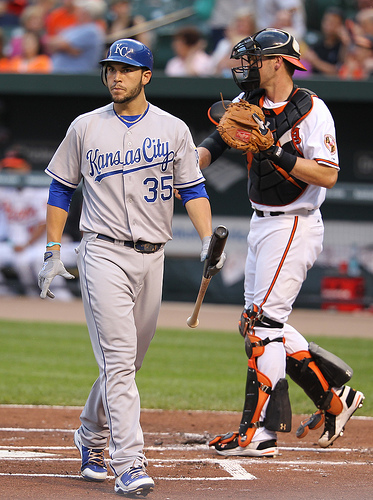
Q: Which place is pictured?
A: It is a field.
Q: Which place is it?
A: It is a field.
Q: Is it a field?
A: Yes, it is a field.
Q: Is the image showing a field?
A: Yes, it is showing a field.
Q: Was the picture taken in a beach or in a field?
A: It was taken at a field.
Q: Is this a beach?
A: No, it is a field.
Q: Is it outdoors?
A: Yes, it is outdoors.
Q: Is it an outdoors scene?
A: Yes, it is outdoors.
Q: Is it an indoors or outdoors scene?
A: It is outdoors.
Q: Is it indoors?
A: No, it is outdoors.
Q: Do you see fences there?
A: No, there are no fences.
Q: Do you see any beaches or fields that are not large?
A: No, there is a field but it is large.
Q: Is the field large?
A: Yes, the field is large.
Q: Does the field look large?
A: Yes, the field is large.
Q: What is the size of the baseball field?
A: The field is large.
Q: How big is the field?
A: The field is large.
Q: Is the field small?
A: No, the field is large.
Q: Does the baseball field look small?
A: No, the field is large.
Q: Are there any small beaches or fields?
A: No, there is a field but it is large.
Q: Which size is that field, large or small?
A: The field is large.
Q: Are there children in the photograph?
A: No, there are no children.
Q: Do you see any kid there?
A: No, there are no children.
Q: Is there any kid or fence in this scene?
A: No, there are no children or fences.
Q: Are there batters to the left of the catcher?
A: Yes, there is a batter to the left of the catcher.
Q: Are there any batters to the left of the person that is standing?
A: Yes, there is a batter to the left of the catcher.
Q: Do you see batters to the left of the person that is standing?
A: Yes, there is a batter to the left of the catcher.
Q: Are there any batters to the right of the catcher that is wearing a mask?
A: No, the batter is to the left of the catcher.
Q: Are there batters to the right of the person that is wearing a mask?
A: No, the batter is to the left of the catcher.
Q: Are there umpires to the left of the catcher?
A: No, there is a batter to the left of the catcher.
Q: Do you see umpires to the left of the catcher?
A: No, there is a batter to the left of the catcher.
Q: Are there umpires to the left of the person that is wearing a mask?
A: No, there is a batter to the left of the catcher.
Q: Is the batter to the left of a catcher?
A: Yes, the batter is to the left of a catcher.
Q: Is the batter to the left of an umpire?
A: No, the batter is to the left of a catcher.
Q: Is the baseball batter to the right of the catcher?
A: No, the batter is to the left of the catcher.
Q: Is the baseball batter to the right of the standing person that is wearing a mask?
A: No, the batter is to the left of the catcher.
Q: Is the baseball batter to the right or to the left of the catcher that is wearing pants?
A: The batter is to the left of the catcher.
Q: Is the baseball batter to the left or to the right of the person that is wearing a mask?
A: The batter is to the left of the catcher.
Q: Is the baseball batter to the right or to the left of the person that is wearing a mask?
A: The batter is to the left of the catcher.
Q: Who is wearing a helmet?
A: The batter is wearing a helmet.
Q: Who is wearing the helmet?
A: The batter is wearing a helmet.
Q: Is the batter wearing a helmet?
A: Yes, the batter is wearing a helmet.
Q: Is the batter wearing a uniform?
A: No, the batter is wearing a helmet.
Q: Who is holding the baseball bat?
A: The batter is holding the baseball bat.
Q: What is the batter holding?
A: The batter is holding the baseball bat.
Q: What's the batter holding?
A: The batter is holding the baseball bat.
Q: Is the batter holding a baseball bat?
A: Yes, the batter is holding a baseball bat.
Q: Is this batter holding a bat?
A: No, the batter is holding a baseball bat.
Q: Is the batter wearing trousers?
A: Yes, the batter is wearing trousers.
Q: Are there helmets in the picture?
A: Yes, there is a helmet.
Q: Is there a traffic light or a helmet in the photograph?
A: Yes, there is a helmet.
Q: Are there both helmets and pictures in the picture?
A: No, there is a helmet but no pictures.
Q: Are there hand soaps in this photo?
A: No, there are no hand soaps.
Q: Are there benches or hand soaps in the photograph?
A: No, there are no hand soaps or benches.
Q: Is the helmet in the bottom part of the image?
A: No, the helmet is in the top of the image.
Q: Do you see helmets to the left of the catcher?
A: Yes, there is a helmet to the left of the catcher.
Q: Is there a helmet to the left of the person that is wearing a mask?
A: Yes, there is a helmet to the left of the catcher.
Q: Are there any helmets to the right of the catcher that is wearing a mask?
A: No, the helmet is to the left of the catcher.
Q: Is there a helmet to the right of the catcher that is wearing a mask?
A: No, the helmet is to the left of the catcher.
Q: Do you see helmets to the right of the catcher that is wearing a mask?
A: No, the helmet is to the left of the catcher.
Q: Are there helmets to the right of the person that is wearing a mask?
A: No, the helmet is to the left of the catcher.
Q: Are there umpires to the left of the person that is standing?
A: No, there is a helmet to the left of the catcher.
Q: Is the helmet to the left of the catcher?
A: Yes, the helmet is to the left of the catcher.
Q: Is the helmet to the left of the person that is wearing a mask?
A: Yes, the helmet is to the left of the catcher.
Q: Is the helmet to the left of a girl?
A: No, the helmet is to the left of the catcher.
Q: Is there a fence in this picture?
A: No, there are no fences.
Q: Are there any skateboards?
A: No, there are no skateboards.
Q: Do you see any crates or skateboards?
A: No, there are no skateboards or crates.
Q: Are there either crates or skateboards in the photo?
A: No, there are no skateboards or crates.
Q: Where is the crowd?
A: The crowd is in the bleachers.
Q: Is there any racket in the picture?
A: No, there are no rackets.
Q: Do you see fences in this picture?
A: No, there are no fences.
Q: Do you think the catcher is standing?
A: Yes, the catcher is standing.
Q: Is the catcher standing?
A: Yes, the catcher is standing.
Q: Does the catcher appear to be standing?
A: Yes, the catcher is standing.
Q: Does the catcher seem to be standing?
A: Yes, the catcher is standing.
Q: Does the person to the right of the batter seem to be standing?
A: Yes, the catcher is standing.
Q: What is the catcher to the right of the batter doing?
A: The catcher is standing.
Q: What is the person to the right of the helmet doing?
A: The catcher is standing.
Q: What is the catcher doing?
A: The catcher is standing.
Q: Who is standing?
A: The catcher is standing.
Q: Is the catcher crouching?
A: No, the catcher is standing.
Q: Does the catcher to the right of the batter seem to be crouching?
A: No, the catcher is standing.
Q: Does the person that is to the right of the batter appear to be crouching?
A: No, the catcher is standing.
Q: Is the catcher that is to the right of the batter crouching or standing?
A: The catcher is standing.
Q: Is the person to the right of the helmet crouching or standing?
A: The catcher is standing.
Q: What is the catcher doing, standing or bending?
A: The catcher is standing.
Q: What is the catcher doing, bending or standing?
A: The catcher is standing.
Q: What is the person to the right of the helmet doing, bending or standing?
A: The catcher is standing.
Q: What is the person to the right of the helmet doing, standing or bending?
A: The catcher is standing.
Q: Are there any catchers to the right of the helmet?
A: Yes, there is a catcher to the right of the helmet.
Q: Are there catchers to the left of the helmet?
A: No, the catcher is to the right of the helmet.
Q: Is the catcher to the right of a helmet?
A: Yes, the catcher is to the right of a helmet.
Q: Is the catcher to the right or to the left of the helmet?
A: The catcher is to the right of the helmet.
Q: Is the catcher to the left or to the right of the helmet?
A: The catcher is to the right of the helmet.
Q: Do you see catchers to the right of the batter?
A: Yes, there is a catcher to the right of the batter.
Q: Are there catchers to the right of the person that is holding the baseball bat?
A: Yes, there is a catcher to the right of the batter.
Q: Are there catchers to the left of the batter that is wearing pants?
A: No, the catcher is to the right of the batter.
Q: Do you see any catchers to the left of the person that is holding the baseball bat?
A: No, the catcher is to the right of the batter.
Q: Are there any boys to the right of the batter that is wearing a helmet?
A: No, there is a catcher to the right of the batter.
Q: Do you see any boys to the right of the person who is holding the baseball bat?
A: No, there is a catcher to the right of the batter.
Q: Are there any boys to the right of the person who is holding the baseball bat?
A: No, there is a catcher to the right of the batter.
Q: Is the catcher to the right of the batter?
A: Yes, the catcher is to the right of the batter.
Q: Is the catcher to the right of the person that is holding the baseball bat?
A: Yes, the catcher is to the right of the batter.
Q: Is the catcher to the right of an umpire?
A: No, the catcher is to the right of the batter.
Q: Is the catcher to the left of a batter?
A: No, the catcher is to the right of a batter.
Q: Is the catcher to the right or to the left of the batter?
A: The catcher is to the right of the batter.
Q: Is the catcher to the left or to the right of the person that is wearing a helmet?
A: The catcher is to the right of the batter.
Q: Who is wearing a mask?
A: The catcher is wearing a mask.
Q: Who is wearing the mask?
A: The catcher is wearing a mask.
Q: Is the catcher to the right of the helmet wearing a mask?
A: Yes, the catcher is wearing a mask.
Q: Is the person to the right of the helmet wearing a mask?
A: Yes, the catcher is wearing a mask.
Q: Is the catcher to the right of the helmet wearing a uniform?
A: No, the catcher is wearing a mask.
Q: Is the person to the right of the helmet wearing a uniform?
A: No, the catcher is wearing a mask.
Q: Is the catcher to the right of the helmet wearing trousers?
A: Yes, the catcher is wearing trousers.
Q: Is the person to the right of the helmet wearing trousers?
A: Yes, the catcher is wearing trousers.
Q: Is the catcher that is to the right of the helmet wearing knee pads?
A: No, the catcher is wearing trousers.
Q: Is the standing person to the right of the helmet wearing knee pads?
A: No, the catcher is wearing trousers.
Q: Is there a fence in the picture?
A: No, there are no fences.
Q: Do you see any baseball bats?
A: Yes, there is a baseball bat.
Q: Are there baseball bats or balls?
A: Yes, there is a baseball bat.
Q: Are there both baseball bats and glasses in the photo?
A: No, there is a baseball bat but no glasses.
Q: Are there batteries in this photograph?
A: No, there are no batteries.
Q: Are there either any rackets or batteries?
A: No, there are no batteries or rackets.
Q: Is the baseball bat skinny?
A: Yes, the baseball bat is skinny.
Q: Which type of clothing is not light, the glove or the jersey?
A: The glove is not light.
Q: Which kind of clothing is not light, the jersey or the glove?
A: The glove is not light.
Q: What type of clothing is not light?
A: The clothing is a glove.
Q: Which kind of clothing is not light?
A: The clothing is a glove.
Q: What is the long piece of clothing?
A: The clothing item is a jersey.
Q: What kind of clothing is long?
A: The clothing is a jersey.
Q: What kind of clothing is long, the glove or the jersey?
A: The jersey is long.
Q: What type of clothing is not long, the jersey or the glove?
A: The glove is not long.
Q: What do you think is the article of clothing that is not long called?
A: The clothing item is a glove.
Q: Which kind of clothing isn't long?
A: The clothing is a glove.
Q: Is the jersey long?
A: Yes, the jersey is long.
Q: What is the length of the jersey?
A: The jersey is long.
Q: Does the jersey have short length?
A: No, the jersey is long.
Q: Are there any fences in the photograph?
A: No, there are no fences.